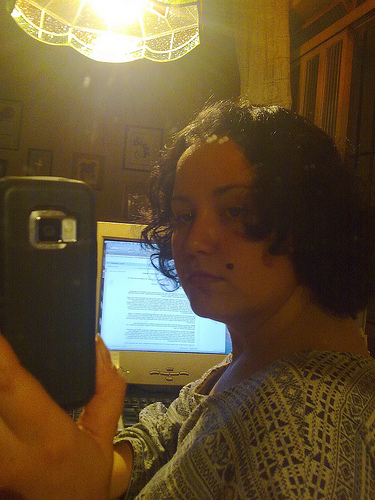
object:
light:
[7, 1, 202, 62]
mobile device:
[0, 174, 100, 410]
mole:
[227, 261, 235, 270]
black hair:
[127, 93, 374, 319]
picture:
[121, 120, 165, 173]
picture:
[71, 149, 107, 188]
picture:
[25, 147, 53, 177]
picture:
[0, 96, 25, 152]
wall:
[0, 0, 239, 225]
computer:
[95, 220, 233, 434]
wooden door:
[289, 26, 354, 165]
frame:
[288, 0, 375, 71]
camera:
[26, 208, 79, 250]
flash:
[26, 207, 79, 250]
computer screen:
[98, 235, 234, 354]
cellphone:
[0, 175, 98, 410]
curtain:
[230, 1, 293, 112]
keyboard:
[120, 395, 186, 422]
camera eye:
[34, 214, 64, 244]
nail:
[94, 331, 112, 369]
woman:
[0, 99, 372, 498]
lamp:
[6, 0, 201, 65]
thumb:
[79, 331, 127, 442]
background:
[0, 1, 373, 223]